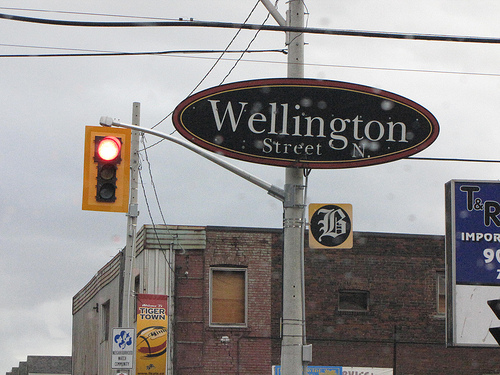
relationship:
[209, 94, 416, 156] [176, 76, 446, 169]
lettering on sign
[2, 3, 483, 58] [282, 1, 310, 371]
power lines attached to pole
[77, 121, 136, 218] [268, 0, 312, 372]
stoplight from pole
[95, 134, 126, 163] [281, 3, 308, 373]
red/traffic light attached to pole